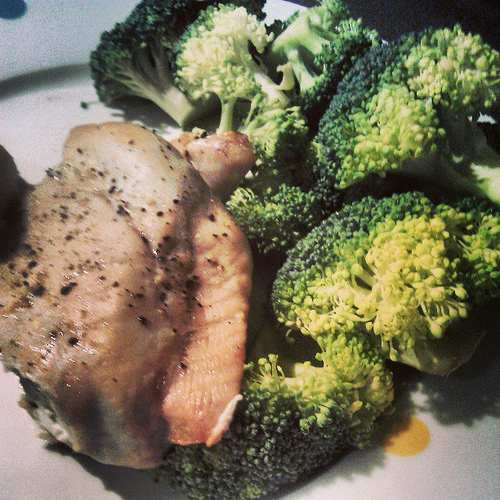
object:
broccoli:
[85, 0, 496, 499]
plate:
[0, 0, 498, 500]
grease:
[377, 413, 430, 460]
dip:
[5, 62, 83, 98]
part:
[169, 0, 499, 415]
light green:
[272, 31, 492, 375]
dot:
[379, 413, 430, 456]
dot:
[0, 0, 27, 22]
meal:
[3, 1, 500, 500]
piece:
[175, 8, 277, 106]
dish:
[0, 0, 499, 499]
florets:
[89, 0, 500, 500]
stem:
[146, 74, 202, 128]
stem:
[448, 137, 500, 204]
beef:
[0, 121, 252, 469]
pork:
[0, 118, 258, 475]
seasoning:
[2, 134, 227, 364]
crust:
[0, 121, 251, 470]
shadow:
[423, 363, 500, 429]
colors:
[86, 5, 500, 499]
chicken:
[0, 117, 256, 470]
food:
[0, 1, 492, 500]